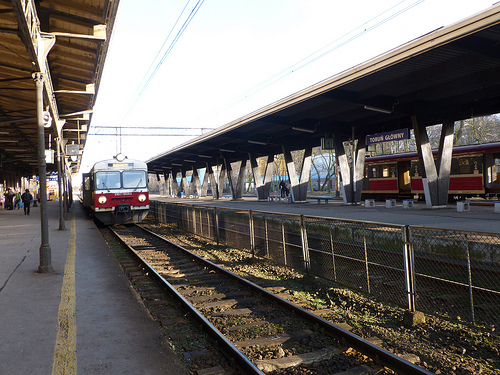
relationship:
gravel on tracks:
[232, 311, 299, 354] [137, 217, 365, 373]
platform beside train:
[20, 243, 122, 364] [75, 150, 162, 217]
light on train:
[135, 188, 147, 206] [78, 152, 150, 225]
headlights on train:
[97, 195, 107, 205] [78, 152, 150, 225]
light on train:
[112, 150, 131, 160] [78, 152, 150, 225]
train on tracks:
[78, 152, 150, 225] [120, 220, 491, 374]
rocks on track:
[228, 318, 286, 338] [144, 240, 330, 374]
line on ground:
[53, 205, 83, 374] [1, 201, 188, 373]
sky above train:
[68, 0, 498, 205] [75, 152, 152, 231]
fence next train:
[240, 205, 322, 271] [78, 152, 150, 225]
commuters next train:
[21, 188, 33, 216] [81, 151, 159, 229]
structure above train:
[295, 56, 424, 110] [362, 137, 499, 204]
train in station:
[78, 152, 150, 225] [1, 2, 191, 374]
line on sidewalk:
[53, 205, 92, 373] [7, 211, 127, 371]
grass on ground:
[266, 279, 368, 321] [282, 282, 365, 352]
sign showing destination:
[92, 140, 179, 178] [107, 153, 139, 172]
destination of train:
[107, 153, 139, 172] [62, 144, 170, 232]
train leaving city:
[348, 144, 498, 203] [9, 14, 496, 365]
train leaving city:
[78, 152, 150, 225] [9, 14, 496, 365]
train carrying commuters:
[78, 152, 150, 225] [100, 177, 134, 189]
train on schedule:
[32, 63, 492, 368] [98, 142, 156, 230]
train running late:
[78, 152, 150, 225] [87, 169, 163, 220]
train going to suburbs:
[78, 152, 150, 225] [39, 55, 462, 366]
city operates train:
[9, 14, 496, 365] [43, 113, 206, 270]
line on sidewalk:
[53, 205, 83, 374] [1, 200, 192, 374]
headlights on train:
[95, 192, 147, 202] [79, 149, 165, 239]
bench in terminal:
[289, 177, 351, 208] [19, 87, 453, 319]